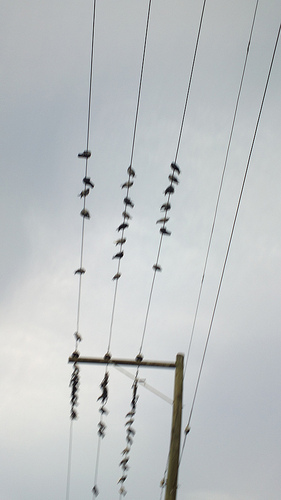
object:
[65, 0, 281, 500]
power lines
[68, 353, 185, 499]
wooden base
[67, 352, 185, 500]
electric pole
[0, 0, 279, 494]
sky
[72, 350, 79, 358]
black object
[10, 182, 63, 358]
white misty cloud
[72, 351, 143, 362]
black connectors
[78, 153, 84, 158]
tail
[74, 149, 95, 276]
bird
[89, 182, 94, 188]
tail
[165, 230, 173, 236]
tail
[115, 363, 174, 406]
striation mark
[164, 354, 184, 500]
pole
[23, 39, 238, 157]
clouds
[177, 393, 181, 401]
splinters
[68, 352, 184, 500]
post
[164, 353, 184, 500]
wood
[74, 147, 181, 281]
group of birds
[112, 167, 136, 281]
bird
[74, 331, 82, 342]
bird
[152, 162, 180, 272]
bird